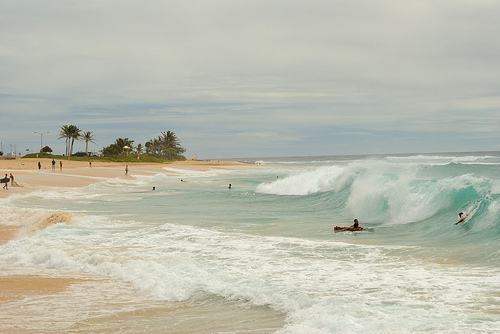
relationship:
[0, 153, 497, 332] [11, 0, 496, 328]
beach in scene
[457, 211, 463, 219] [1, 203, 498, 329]
person riding current to shore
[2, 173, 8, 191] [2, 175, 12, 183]
person carrying surfboard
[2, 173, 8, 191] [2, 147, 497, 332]
person on beach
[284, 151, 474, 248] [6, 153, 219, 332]
water pounding towards shore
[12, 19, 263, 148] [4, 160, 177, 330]
sky above sand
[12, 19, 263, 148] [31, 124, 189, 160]
sky above vegetation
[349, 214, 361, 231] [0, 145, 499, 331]
someone surfing in water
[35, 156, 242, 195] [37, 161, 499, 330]
people swimming in water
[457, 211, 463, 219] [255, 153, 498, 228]
person riding wave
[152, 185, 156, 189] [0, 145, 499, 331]
people enjoying water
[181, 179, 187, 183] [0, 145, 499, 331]
people enjoying water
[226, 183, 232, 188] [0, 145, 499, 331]
people enjoying water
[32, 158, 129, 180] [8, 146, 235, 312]
people on beach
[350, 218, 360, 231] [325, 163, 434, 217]
someone on wave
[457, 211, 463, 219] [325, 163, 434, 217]
person on wave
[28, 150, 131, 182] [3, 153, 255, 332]
people walking along beach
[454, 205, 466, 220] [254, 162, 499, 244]
person riding wave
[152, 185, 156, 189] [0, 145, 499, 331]
people in water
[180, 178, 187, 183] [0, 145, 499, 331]
people in water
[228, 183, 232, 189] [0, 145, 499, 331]
people in water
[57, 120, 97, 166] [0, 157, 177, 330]
palmtrees on sand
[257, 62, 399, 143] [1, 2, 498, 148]
sky poking through clouds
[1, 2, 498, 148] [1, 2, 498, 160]
clouds covering sky